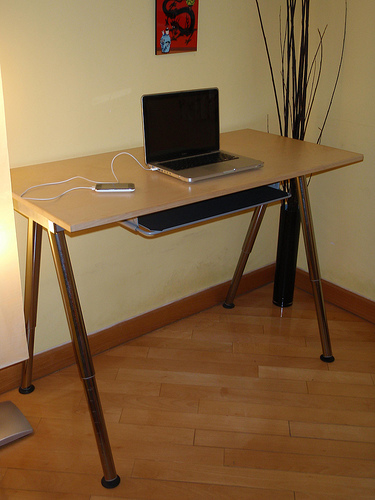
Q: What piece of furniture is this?
A: A desk.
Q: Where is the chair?
A: There isn't one.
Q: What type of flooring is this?
A: Wooden.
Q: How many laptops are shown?
A: 1.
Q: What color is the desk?
A: Light brown.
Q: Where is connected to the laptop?
A: A cell phone.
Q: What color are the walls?
A: Yellowish.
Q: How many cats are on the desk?
A: None.